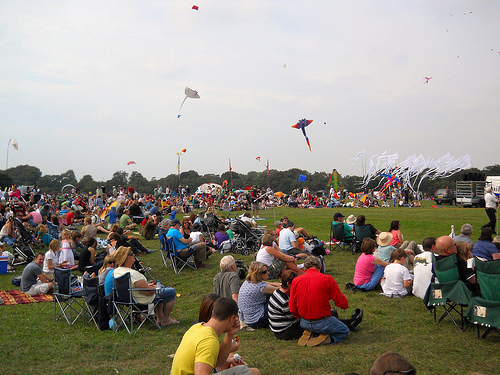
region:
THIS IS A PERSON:
[196, 299, 248, 361]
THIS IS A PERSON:
[294, 250, 349, 317]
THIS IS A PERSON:
[387, 250, 420, 295]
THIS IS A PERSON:
[352, 238, 377, 287]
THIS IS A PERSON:
[394, 217, 405, 245]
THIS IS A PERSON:
[273, 214, 305, 242]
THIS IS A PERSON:
[335, 205, 347, 248]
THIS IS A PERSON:
[173, 210, 183, 250]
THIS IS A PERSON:
[58, 234, 75, 270]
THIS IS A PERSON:
[46, 236, 63, 276]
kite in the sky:
[172, 83, 200, 118]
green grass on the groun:
[41, 332, 80, 373]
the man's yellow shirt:
[176, 315, 216, 371]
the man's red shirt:
[286, 274, 351, 316]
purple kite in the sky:
[291, 109, 322, 153]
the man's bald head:
[431, 234, 450, 250]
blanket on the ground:
[3, 289, 50, 310]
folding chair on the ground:
[107, 271, 158, 324]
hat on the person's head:
[113, 243, 129, 267]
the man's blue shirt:
[163, 229, 187, 252]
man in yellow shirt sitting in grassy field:
[163, 295, 265, 374]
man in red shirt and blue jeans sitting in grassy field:
[283, 251, 355, 351]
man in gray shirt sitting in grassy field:
[208, 251, 247, 331]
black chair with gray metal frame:
[108, 270, 166, 335]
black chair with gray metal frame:
[69, 269, 111, 330]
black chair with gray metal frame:
[50, 262, 95, 328]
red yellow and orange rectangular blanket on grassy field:
[0, 284, 76, 306]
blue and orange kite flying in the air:
[289, 114, 317, 154]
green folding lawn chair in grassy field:
[421, 248, 476, 334]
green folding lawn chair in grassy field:
[459, 251, 498, 344]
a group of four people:
[208, 251, 366, 351]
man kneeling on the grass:
[290, 251, 355, 349]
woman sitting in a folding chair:
[106, 244, 181, 339]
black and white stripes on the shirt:
[264, 285, 297, 335]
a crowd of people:
[1, 168, 497, 374]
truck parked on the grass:
[452, 176, 485, 209]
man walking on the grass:
[478, 183, 498, 230]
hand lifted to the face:
[222, 312, 242, 338]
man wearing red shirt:
[292, 240, 350, 352]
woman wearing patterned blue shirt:
[230, 250, 285, 332]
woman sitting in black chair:
[108, 243, 178, 329]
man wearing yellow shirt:
[170, 295, 251, 373]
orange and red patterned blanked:
[3, 282, 56, 312]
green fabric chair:
[467, 256, 497, 351]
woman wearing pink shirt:
[345, 231, 390, 298]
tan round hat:
[372, 226, 398, 249]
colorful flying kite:
[291, 103, 322, 155]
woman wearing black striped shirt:
[262, 259, 309, 339]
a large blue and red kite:
[290, 115, 320, 151]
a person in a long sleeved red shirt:
[290, 264, 348, 320]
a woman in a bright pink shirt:
[350, 238, 388, 292]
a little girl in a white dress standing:
[58, 226, 79, 271]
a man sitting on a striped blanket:
[0, 253, 54, 307]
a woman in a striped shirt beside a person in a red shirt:
[266, 266, 299, 337]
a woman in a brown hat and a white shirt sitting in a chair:
[111, 248, 178, 315]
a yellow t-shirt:
[170, 320, 225, 373]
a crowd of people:
[5, 184, 498, 373]